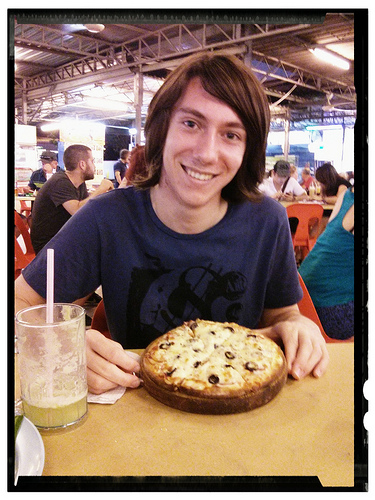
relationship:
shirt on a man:
[54, 178, 321, 339] [31, 44, 320, 359]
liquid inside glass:
[22, 391, 89, 429] [12, 300, 90, 434]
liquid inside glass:
[22, 391, 88, 429] [23, 305, 88, 423]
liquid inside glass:
[22, 391, 88, 429] [14, 301, 109, 440]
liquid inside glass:
[22, 391, 88, 429] [21, 277, 117, 441]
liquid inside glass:
[22, 391, 88, 429] [15, 298, 95, 435]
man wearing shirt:
[5, 51, 333, 395] [22, 182, 313, 348]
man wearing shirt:
[5, 51, 333, 395] [29, 183, 302, 358]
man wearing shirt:
[5, 51, 333, 395] [27, 52, 323, 377]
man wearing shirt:
[25, 51, 333, 383] [19, 178, 306, 350]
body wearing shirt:
[63, 173, 318, 407] [213, 227, 237, 254]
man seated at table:
[5, 51, 333, 395] [35, 225, 374, 430]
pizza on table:
[137, 317, 287, 416] [12, 341, 356, 485]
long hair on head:
[102, 43, 276, 197] [160, 78, 249, 207]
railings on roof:
[37, 30, 143, 89] [71, 27, 145, 71]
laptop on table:
[15, 472, 336, 497] [24, 331, 354, 486]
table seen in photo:
[31, 331, 354, 470] [13, 14, 356, 485]